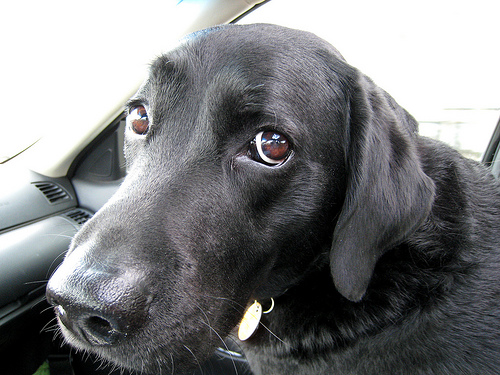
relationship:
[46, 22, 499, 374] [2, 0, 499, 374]
dog sitting in car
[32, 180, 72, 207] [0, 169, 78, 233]
ac duct attached to dashboard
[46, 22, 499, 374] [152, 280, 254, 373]
dog has cheek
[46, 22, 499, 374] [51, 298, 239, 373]
dog has mouth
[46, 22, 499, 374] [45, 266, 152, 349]
dog has nose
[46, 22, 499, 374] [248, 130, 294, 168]
dog has eye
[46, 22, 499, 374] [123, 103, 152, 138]
dog has eye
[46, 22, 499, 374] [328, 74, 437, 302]
dog has ear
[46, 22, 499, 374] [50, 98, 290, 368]
dog has face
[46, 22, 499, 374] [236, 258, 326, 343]
dog has collar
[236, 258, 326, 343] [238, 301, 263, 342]
collar has tag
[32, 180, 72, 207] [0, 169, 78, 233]
ac duct on dashboard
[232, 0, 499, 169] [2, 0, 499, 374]
window attached to car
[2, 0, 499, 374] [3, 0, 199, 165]
car has windshield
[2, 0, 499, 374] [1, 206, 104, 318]
car has glovebox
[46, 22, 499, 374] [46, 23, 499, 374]
dog has fur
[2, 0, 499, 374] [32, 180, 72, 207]
car has ac duct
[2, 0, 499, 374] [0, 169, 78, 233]
car has dashboard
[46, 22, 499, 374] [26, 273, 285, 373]
dog has whiskers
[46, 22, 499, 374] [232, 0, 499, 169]
dog next to window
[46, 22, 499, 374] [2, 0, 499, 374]
dog in car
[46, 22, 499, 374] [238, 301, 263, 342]
dog has tag